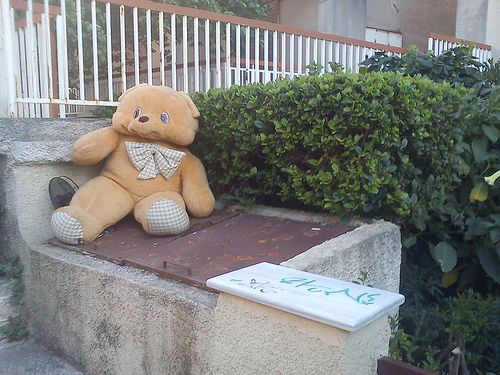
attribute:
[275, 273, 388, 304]
grafitti — green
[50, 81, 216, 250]
bear — brown, light brown, forward, stuffed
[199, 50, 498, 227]
shrubs — green, branches, leafed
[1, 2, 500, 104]
railing — white, brown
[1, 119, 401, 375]
wall — concrete, grey, small, light grey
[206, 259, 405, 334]
tile — rectangular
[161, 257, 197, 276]
handle — rusted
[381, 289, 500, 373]
plant — green, leafed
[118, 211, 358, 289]
door — metal, rusty, rusted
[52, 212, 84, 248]
foot — gingham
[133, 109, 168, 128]
eyes — brown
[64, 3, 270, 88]
tree — distant